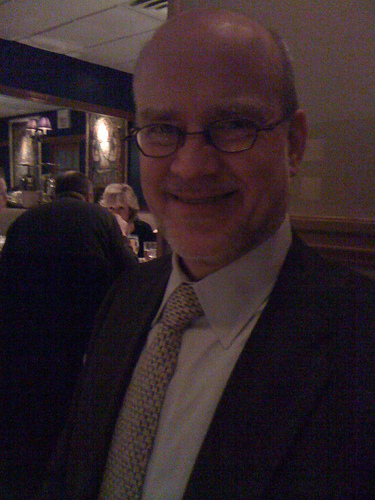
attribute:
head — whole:
[130, 5, 306, 258]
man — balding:
[103, 12, 339, 498]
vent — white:
[123, 2, 186, 30]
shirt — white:
[101, 263, 262, 466]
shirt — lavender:
[141, 209, 291, 499]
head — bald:
[135, 9, 298, 266]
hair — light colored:
[95, 181, 140, 218]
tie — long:
[108, 276, 194, 495]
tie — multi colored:
[100, 287, 204, 498]